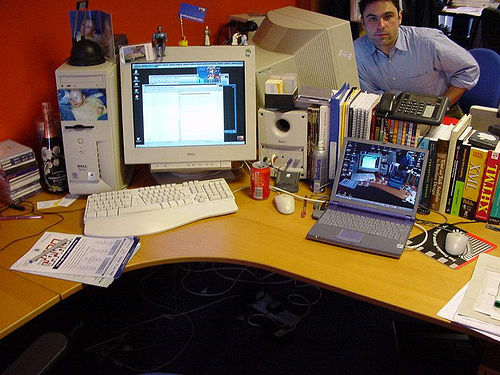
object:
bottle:
[36, 102, 67, 194]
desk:
[0, 167, 500, 340]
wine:
[37, 103, 69, 195]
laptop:
[304, 136, 429, 259]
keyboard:
[84, 177, 239, 238]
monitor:
[118, 45, 257, 173]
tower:
[55, 55, 135, 194]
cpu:
[54, 56, 135, 195]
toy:
[151, 26, 168, 61]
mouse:
[445, 229, 470, 256]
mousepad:
[407, 222, 498, 271]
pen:
[301, 195, 308, 218]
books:
[307, 81, 500, 226]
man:
[353, 0, 481, 106]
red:
[477, 236, 483, 241]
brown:
[261, 223, 289, 246]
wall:
[2, 6, 71, 62]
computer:
[54, 42, 258, 194]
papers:
[9, 231, 142, 288]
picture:
[69, 9, 116, 63]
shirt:
[351, 24, 481, 98]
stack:
[1, 138, 44, 205]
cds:
[0, 139, 42, 205]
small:
[304, 202, 416, 260]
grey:
[58, 237, 69, 245]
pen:
[29, 238, 68, 263]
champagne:
[35, 102, 69, 194]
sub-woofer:
[258, 108, 309, 179]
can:
[249, 161, 270, 200]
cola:
[250, 161, 270, 200]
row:
[419, 138, 500, 222]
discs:
[0, 139, 42, 205]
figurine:
[152, 26, 168, 61]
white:
[289, 19, 320, 45]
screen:
[329, 137, 429, 221]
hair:
[357, 3, 399, 18]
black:
[398, 98, 425, 114]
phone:
[375, 90, 451, 126]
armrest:
[0, 332, 67, 375]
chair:
[457, 47, 500, 116]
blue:
[483, 82, 492, 96]